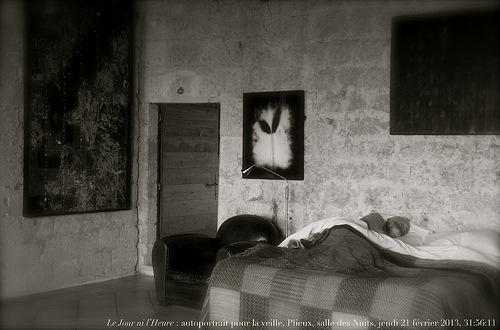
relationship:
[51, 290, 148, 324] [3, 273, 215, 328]
tiles on floor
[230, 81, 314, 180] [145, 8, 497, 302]
picture hanging wall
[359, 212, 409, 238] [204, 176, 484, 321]
man sleeping bed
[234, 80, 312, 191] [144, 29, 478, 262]
frame on wall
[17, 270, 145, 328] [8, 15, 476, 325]
floor in bedroom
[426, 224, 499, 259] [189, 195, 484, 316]
pillow in bed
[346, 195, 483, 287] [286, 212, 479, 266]
sheets in bed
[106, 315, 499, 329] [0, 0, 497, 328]
description of photo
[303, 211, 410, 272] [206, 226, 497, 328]
man asleep in bed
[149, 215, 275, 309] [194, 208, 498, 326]
chair beside bed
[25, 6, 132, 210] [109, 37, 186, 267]
painting on wall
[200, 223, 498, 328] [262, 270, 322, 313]
bedspread with print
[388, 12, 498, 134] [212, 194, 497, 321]
painting hanging above bed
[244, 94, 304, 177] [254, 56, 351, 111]
painting hanging on wall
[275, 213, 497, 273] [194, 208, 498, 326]
white sheet on bed